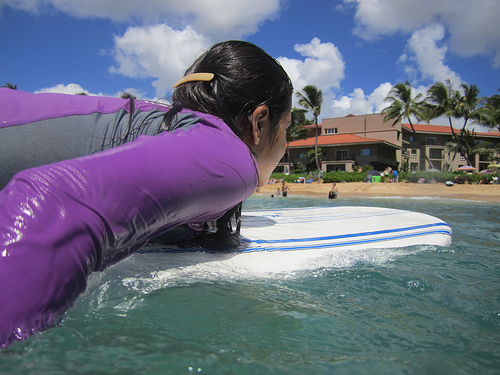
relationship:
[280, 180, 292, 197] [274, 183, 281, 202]
people walking with child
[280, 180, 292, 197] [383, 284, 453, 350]
people walking into water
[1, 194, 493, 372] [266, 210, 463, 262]
water on surfboard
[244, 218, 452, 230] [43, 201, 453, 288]
blue stripe on surfboard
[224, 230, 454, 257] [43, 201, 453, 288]
blue stripe on surfboard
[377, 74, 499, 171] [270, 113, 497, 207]
trees in front building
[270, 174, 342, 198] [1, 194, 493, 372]
people in water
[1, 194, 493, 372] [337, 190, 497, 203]
water going on shoreline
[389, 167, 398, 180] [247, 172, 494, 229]
people on shore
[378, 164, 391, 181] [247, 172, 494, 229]
people on shore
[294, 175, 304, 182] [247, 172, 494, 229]
people on shore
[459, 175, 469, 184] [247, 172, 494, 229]
people on shore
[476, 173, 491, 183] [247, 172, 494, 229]
people on shore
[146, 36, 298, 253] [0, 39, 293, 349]
hair on woman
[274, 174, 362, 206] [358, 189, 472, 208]
people on shore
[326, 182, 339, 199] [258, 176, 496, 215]
people on shore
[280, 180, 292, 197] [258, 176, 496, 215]
people on shore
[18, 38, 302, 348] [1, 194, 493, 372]
woman in water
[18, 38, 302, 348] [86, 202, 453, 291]
woman on board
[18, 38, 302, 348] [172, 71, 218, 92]
woman wears wooden barrett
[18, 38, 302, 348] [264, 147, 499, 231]
woman swims to beach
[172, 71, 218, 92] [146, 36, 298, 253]
wooden barrett in hair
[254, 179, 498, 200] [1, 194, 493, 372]
sand near water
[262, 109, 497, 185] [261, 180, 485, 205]
building sits on beach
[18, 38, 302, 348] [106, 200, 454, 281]
woman lying on surfboard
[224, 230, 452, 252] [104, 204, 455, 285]
blue stripe on surfboard